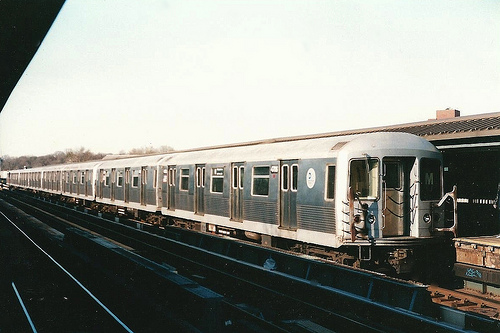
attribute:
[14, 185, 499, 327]
rails — rusty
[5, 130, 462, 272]
train — long 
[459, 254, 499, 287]
graffiti — small, area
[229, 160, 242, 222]
door — electronic, sliding, side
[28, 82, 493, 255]
train — each, car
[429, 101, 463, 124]
chimney — building, in background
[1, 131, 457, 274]
metro train — long, silver 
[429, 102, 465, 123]
chimney — small, portion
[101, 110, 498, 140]
roof — brown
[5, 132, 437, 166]
roof — white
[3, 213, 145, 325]
rail — dark 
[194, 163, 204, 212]
doors — side, electronic, sliding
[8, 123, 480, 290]
train — passenger, very long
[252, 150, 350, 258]
doors — electronic , sliding  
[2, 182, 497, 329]
train tracks — Empty, metal 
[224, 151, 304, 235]
doors — 4